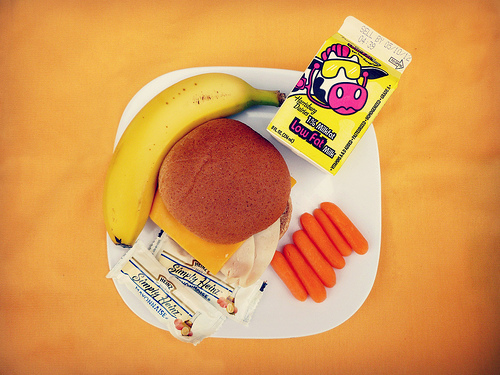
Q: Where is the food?
A: Plate.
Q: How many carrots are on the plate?
A: 6.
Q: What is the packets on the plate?
A: Simply Heinz.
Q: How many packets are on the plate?
A: 2.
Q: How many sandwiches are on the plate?
A: One.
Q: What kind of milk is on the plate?
A: 1%.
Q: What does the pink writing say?
A: Low Fat.